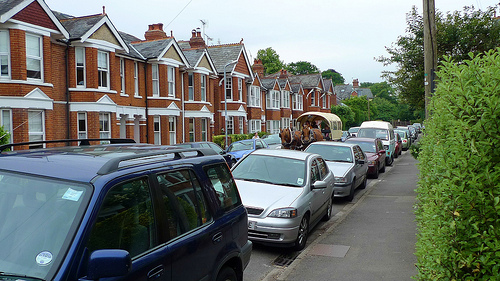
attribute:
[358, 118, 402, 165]
van — parked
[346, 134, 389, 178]
car — parked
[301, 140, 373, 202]
car — parked, white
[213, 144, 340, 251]
car — parked, white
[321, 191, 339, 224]
tire — round, black, inflated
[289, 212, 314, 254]
tire — round, black, inflated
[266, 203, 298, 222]
headlight — off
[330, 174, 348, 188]
headlight — off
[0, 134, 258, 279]
van — parked, blue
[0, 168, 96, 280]
windshield — tinted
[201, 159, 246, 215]
window — tinted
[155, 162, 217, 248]
window — tinted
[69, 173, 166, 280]
window — tinted